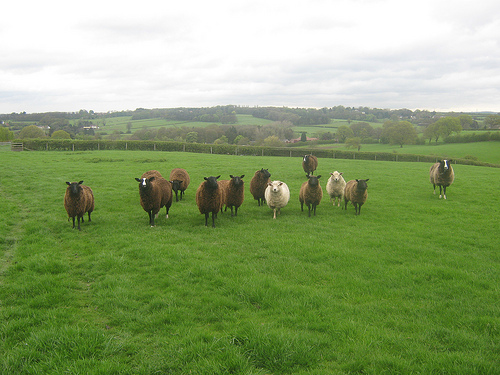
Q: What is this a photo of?
A: Sheep.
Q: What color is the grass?
A: Green.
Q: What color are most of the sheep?
A: Brown.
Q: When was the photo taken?
A: Daytime.